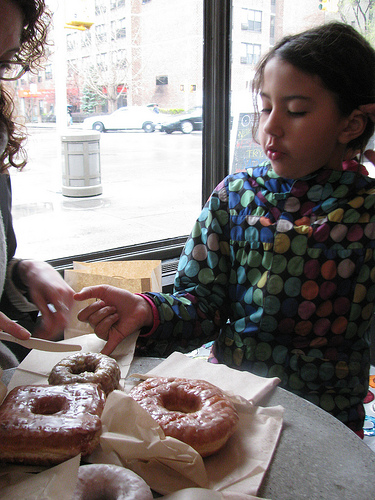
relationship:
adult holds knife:
[1, 1, 75, 368] [1, 331, 82, 353]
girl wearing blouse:
[74, 22, 375, 441] [136, 162, 375, 441]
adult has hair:
[1, 1, 75, 368] [1, 1, 53, 176]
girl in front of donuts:
[74, 22, 375, 441] [1, 353, 239, 500]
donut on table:
[50, 352, 122, 393] [1, 355, 375, 500]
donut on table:
[1, 381, 105, 465] [1, 355, 375, 500]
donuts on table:
[35, 461, 159, 500] [1, 355, 375, 500]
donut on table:
[128, 376, 239, 458] [1, 355, 375, 500]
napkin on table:
[136, 351, 281, 408] [1, 355, 375, 500]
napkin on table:
[6, 327, 139, 400] [1, 355, 375, 500]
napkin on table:
[101, 389, 285, 495] [1, 355, 375, 500]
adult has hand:
[1, 1, 75, 368] [1, 310, 32, 342]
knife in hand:
[1, 331, 82, 353] [1, 310, 32, 342]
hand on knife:
[1, 310, 32, 342] [1, 331, 82, 353]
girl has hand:
[74, 22, 375, 441] [72, 281, 151, 357]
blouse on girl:
[136, 162, 375, 441] [74, 22, 375, 441]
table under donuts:
[1, 355, 375, 500] [1, 353, 239, 500]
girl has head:
[74, 22, 375, 441] [252, 23, 375, 181]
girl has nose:
[74, 22, 375, 441] [263, 110, 284, 138]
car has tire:
[161, 111, 202, 136] [180, 121, 194, 136]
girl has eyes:
[74, 22, 375, 441] [259, 98, 311, 119]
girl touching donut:
[74, 22, 375, 441] [50, 352, 122, 393]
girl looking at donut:
[74, 22, 375, 441] [50, 352, 122, 393]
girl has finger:
[74, 22, 375, 441] [99, 335, 120, 356]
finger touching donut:
[99, 335, 120, 356] [50, 352, 122, 393]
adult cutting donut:
[1, 1, 75, 368] [50, 352, 122, 393]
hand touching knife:
[1, 310, 32, 342] [1, 331, 82, 353]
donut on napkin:
[128, 376, 239, 458] [101, 389, 285, 495]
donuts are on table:
[1, 353, 239, 500] [1, 355, 375, 500]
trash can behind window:
[59, 133, 104, 199] [17, 0, 233, 253]